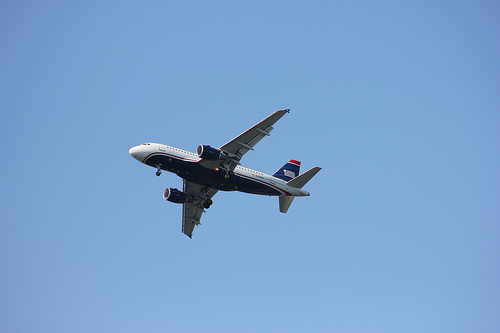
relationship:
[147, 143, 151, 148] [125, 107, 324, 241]
window on airplane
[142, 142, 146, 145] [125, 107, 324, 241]
window on airplane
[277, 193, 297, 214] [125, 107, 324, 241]
tail wing on airplane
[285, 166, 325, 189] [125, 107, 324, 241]
tail on airplane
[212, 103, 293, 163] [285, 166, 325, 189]
white wing on tail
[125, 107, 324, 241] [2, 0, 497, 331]
airplane under clear sky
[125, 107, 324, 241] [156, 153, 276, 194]
airplane has stripe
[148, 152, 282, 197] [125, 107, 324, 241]
underbody of airplane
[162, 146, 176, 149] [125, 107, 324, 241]
window on side of airplane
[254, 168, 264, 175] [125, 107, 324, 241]
window on side of airplane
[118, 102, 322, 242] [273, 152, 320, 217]
airplane has tail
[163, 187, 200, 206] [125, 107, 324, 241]
engine on airplane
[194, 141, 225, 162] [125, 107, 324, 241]
engine on airplane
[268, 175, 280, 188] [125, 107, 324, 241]
door on airplane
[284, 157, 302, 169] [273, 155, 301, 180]
stripe on tail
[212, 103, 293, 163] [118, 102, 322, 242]
white wing on airplane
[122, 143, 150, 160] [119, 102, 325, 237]
nose on front of plane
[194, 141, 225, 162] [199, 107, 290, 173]
engine in front wing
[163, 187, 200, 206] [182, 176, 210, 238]
engine in front wing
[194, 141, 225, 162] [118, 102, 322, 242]
engine on airplane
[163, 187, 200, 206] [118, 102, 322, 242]
engine on airplane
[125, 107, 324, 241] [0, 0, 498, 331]
airplane in clear sky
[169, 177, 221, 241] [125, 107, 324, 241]
white wing on airplane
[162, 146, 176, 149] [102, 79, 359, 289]
window on plane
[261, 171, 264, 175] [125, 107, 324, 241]
window on airplane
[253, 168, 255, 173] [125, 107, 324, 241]
window on airplane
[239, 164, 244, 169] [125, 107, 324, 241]
window on airplane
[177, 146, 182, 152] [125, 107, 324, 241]
window on airplane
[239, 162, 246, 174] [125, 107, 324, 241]
window on airplane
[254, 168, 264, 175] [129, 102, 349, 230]
window on plane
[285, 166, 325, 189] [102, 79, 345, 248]
tail of plane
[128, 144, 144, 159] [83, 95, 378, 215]
nose of plane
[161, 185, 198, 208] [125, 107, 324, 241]
engine on other side airplane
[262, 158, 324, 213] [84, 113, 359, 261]
tail of plane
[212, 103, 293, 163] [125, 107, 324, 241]
white wing of a airplane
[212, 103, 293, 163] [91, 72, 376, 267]
white wing of a airplane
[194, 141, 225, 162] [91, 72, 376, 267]
engine on airplane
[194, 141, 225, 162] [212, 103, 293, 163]
engine on white wing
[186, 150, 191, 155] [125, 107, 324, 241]
window on airplane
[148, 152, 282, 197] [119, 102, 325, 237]
underbody of plane